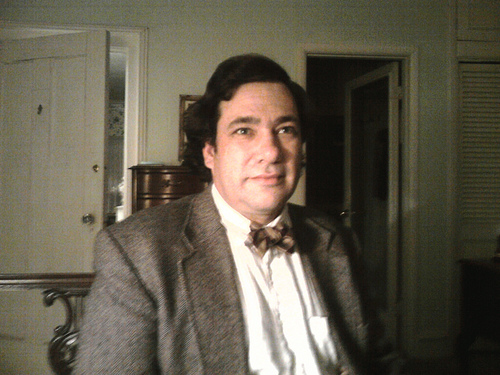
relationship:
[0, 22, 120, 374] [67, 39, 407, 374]
door open behind man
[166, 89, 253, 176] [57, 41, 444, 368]
picture behind man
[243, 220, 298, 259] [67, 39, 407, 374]
bow tie on man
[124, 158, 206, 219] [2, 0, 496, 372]
amoire in room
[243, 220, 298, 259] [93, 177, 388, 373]
bow tie on shirt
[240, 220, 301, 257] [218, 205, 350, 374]
bow tie on shirt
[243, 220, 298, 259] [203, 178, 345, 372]
bow tie on shirt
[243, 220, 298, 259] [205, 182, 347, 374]
bow tie on man's shirt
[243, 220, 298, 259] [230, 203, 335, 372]
bow tie on shirt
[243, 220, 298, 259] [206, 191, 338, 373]
bow tie on shirt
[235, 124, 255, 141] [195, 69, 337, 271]
eye of person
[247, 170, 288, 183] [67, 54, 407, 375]
mouth of man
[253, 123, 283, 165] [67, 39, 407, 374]
nose of man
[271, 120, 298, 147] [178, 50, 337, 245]
eye of man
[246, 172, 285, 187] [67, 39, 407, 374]
mouth of man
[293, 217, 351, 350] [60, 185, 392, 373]
lapel of jacket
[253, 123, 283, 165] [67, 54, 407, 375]
nose of man